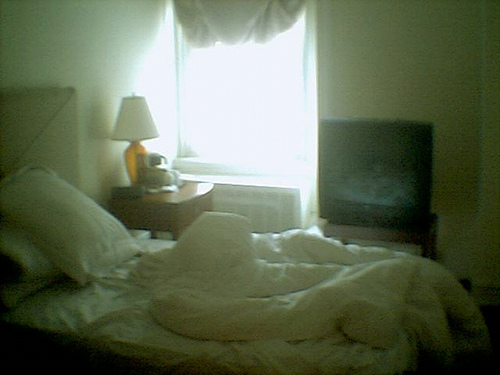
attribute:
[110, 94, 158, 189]
lamp — amber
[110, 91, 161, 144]
shade — white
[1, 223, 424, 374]
bed — messy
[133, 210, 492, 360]
white blankets — messy, wrinkled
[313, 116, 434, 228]
tv — small, tubular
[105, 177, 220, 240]
nightstand — brown, curved, wooden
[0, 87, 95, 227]
headboard — white, tan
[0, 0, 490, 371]
room — messy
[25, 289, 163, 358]
sheets — wrinkled